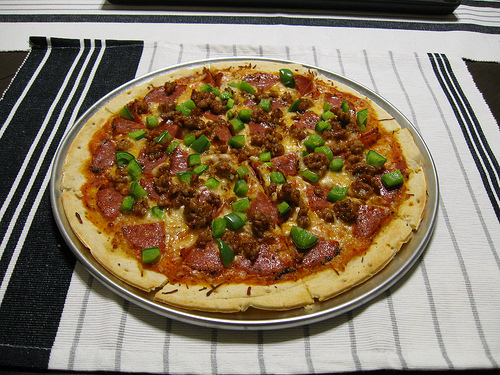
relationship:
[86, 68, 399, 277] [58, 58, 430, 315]
meat on pizza